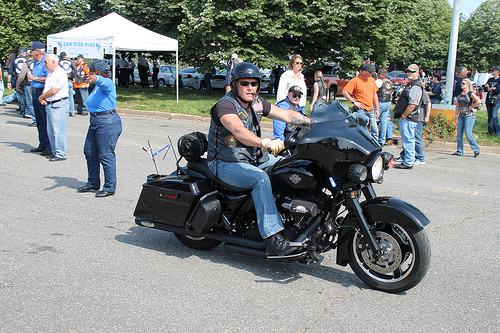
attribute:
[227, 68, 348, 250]
man — looking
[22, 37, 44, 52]
hat — Blue, man's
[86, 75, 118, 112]
shirt — blue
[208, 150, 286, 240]
jeans — blue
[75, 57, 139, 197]
woman — pointing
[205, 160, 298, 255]
jeans — blue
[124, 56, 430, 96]
cars — parked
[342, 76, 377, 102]
shirt — orange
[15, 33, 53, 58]
hat — black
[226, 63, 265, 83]
helmet. — black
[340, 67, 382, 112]
shirt — orange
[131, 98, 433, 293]
motorcycle — black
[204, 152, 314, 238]
jeans — blue 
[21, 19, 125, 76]
sign — white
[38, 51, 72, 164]
man — older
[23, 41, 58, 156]
man — older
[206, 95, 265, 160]
vest — dark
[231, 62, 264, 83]
helmet — black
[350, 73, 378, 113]
shirt — orange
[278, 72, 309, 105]
shirt — white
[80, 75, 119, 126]
shirt — blue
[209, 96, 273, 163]
vest — black